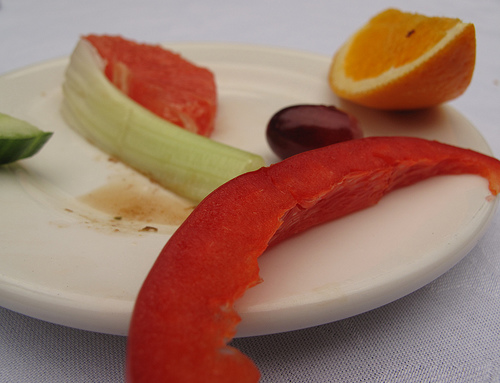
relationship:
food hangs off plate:
[123, 304, 257, 381] [2, 41, 495, 337]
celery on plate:
[58, 33, 268, 204] [2, 41, 495, 337]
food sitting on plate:
[264, 100, 362, 158] [2, 41, 495, 337]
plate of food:
[2, 27, 499, 364] [1, 6, 498, 381]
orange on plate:
[328, 7, 475, 112] [2, 41, 495, 337]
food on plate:
[264, 100, 362, 158] [2, 41, 495, 337]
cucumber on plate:
[1, 103, 58, 168] [2, 41, 495, 337]